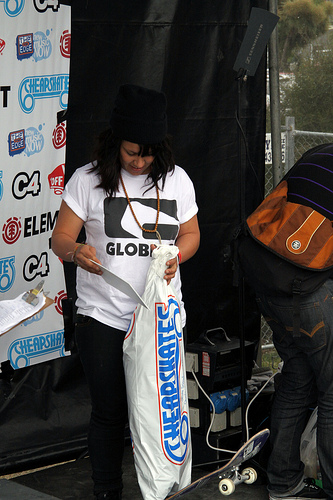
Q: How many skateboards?
A: One.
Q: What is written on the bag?
A: Cheapskates.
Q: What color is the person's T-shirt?
A: Black and white.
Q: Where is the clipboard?
A: Left.